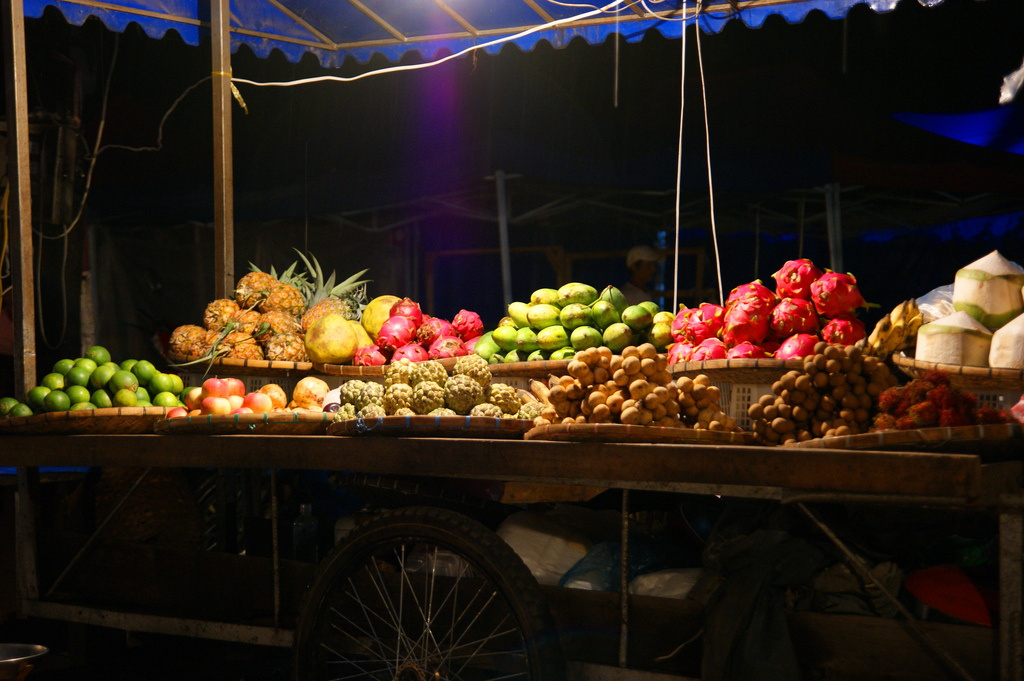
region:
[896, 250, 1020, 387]
bowl filled with trimmed green coconuts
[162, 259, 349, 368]
stack of fresh pineapples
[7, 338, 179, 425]
large pile of limes on tray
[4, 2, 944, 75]
bright blue awning of cart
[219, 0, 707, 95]
light cords on top of fruit cart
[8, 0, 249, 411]
two poles supporting awning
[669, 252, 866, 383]
dragon fruit on large, wooden tray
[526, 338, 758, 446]
cluster of brown fruit on tray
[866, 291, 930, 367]
bananas on tray behind dragon fruit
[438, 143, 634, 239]
a view of black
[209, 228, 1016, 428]
a view of fruits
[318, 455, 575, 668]
a view of tire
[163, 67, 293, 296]
a view of pole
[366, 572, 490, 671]
a view of spokes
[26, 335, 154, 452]
a big pile of limes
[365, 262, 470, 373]
a big pile of pomegranite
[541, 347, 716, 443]
a big pile of oranges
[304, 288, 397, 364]
a big pile of grapefruits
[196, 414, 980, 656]
a table that is wooden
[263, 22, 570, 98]
a tent that is purple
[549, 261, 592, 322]
green fruit in pile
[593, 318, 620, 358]
green fruit in pile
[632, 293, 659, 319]
green fruit in pile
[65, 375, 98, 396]
green fruit in pile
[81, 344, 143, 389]
green fruit in pile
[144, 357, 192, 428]
green fruit in pile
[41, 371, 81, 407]
green fruit in pile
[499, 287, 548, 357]
green fruit in pile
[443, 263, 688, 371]
a pile of green fruit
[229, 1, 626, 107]
a thin white cord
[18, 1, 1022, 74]
top of the tent is blue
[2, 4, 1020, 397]
the sky is pitch black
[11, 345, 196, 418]
a pile of green apples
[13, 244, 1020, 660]
food on a table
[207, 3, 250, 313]
pole supporting the tent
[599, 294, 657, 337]
avocado on the stand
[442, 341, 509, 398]
pineapple on the stand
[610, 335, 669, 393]
potato on the stand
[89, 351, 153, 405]
lime on the stand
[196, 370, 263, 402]
tomato on the stand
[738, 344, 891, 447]
stack of potatoes on table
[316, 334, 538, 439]
stack of fruit on counter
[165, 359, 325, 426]
stack of apples on table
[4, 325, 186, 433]
stack of pears on table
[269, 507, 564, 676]
tire propped in front of table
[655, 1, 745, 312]
string hanging from tent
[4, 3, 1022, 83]
canopy over fruit table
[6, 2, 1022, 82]
canopy over table is blue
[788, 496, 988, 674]
brown stick under table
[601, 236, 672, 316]
man standing behind counter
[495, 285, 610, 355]
green fruit in stand at market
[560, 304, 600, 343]
green fruit in stand at market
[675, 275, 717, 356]
red fruit in stand at market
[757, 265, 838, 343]
red fruit in stand at market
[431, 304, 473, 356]
red fruit in stand at market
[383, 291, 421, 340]
red fruit in stand at market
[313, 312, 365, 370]
yellow fruit in stand at market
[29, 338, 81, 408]
green fruit in stand at market